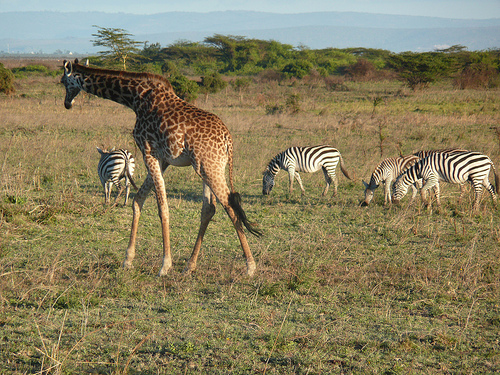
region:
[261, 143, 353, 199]
zebra is eating grass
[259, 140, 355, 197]
zebra is black and white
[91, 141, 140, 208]
zebra is facing away from camera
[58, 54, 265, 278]
giraffe is taller than zebras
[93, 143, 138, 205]
zebra is facing away from giraffe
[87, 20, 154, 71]
tree is behind giraffe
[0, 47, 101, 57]
city is on the horizon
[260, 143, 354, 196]
zebra is standing still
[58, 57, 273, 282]
giraffe has black hair on tail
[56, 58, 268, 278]
giraffe has lots of spots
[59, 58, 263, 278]
brown and tan giraffe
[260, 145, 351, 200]
black and white zebra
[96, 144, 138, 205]
zebra standing in grass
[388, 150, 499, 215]
zebra eating green grass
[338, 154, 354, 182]
grey tail on zebra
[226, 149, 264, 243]
brown and black giraffe tail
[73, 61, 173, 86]
brown mane of giraffe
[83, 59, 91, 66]
white ear on giraffe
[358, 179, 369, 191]
white ear on zebra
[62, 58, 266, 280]
giraffe walking in grass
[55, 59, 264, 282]
a giraffe is walking in a field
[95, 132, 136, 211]
back view of a zebra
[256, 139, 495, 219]
three zebras grazing in the grass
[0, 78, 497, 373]
large savannah housing zebras and a giraffe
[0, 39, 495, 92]
trees on the ground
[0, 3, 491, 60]
mountains way in the distance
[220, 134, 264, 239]
tail on the giraffe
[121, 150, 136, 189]
tail of a zebra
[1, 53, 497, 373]
large area of open land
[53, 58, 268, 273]
the giraffe is bending his neck horizontally forward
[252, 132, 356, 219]
zebra eating the grass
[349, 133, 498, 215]
two zebras eating the grass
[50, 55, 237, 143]
giraffe walking in the field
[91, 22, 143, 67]
green tree in the background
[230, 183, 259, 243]
black on the tip of the tail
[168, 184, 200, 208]
shadow on the ground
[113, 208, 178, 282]
legs of the giraffe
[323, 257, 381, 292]
brown patches on the ground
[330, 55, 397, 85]
brown bushes in the background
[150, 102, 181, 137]
spots on the giraffe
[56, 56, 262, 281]
The giraffe is very tall.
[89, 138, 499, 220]
The zebras are striped.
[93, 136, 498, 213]
The zebras are grazing.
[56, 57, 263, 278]
The giraffe is spotted.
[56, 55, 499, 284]
The animals are plant-eaters.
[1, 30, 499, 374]
The fields are covered in grass.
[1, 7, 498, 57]
The mountains overlook the fields.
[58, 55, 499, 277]
The animals have long tails.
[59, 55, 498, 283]
The animals are equines.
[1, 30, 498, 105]
The trees are tall.